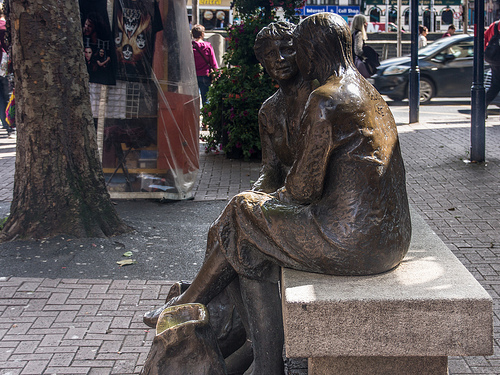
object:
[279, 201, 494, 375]
bench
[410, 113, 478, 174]
path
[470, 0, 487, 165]
post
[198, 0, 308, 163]
bush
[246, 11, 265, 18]
stem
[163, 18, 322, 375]
man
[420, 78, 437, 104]
wheel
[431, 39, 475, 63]
mirror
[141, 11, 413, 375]
sculpture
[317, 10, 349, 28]
sunshine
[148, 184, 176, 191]
paper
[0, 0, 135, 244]
trunk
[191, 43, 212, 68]
strap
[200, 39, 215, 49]
shoulder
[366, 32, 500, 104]
car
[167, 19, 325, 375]
statues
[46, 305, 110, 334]
bricks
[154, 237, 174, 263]
ground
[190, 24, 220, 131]
woman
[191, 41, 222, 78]
shirt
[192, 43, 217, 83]
purse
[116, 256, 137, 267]
leaves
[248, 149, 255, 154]
flowers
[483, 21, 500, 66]
backpack